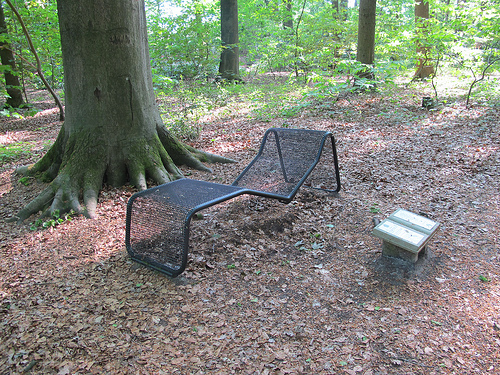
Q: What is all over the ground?
A: Dead leaves.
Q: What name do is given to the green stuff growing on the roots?
A: Moss.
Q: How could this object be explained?
A: Identification plaques.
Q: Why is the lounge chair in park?
A: Someone left it.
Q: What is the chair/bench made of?
A: Black mesh metal.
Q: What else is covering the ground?
A: Pine needles.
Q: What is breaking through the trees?
A: Sunlight.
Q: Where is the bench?
A: In the woods.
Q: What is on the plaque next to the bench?
A: Information.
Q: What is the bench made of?
A: Metal.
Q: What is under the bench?
A: Dead leaves.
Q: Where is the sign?
A: On the right side of the bench.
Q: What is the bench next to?
A: A very large tree.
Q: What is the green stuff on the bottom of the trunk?
A: Moss.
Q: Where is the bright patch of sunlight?
A: On the top right.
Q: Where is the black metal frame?
A: Forest.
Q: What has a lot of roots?
A: Tree trunk.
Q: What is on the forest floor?
A: Dead leaves.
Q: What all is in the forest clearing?
A: Debris.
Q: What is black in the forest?
A: Chair.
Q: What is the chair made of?
A: Metal.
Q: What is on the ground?
A: A metal chair.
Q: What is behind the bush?
A: Brown tree trunks.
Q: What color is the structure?
A: Black.